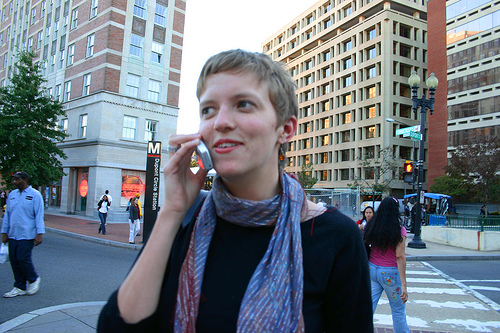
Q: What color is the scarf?
A: Blue.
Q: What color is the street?
A: Gray.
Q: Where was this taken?
A: City street.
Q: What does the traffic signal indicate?
A: Don't walk.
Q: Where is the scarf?
A: Around the woman's neck.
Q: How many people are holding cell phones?
A: 1.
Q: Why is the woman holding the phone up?
A: Talking.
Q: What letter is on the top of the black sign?
A: M.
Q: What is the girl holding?
A: Cell phone.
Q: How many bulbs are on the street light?
A: 2.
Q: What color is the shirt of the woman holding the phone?
A: Black.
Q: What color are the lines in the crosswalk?
A: White.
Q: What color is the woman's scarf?
A: Blue.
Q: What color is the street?
A: Gray.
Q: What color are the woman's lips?
A: Pink.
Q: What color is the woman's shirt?
A: Black.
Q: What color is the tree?
A: Green.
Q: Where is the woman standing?
A: On the sidewalk.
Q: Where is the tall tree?
A: On the left.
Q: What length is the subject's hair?
A: Short.